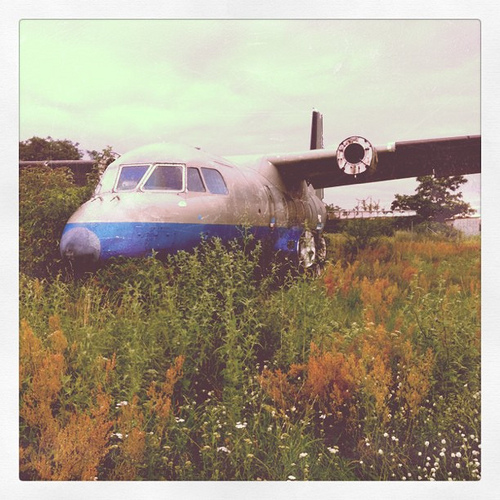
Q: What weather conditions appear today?
A: It is cloudy.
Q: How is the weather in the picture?
A: It is cloudy.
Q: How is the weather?
A: It is cloudy.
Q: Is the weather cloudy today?
A: Yes, it is cloudy.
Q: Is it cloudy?
A: Yes, it is cloudy.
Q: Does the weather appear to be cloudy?
A: Yes, it is cloudy.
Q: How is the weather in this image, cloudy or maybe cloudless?
A: It is cloudy.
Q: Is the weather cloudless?
A: No, it is cloudy.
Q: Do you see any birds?
A: No, there are no birds.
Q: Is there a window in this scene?
A: Yes, there is a window.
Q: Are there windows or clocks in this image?
A: Yes, there is a window.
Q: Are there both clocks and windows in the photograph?
A: No, there is a window but no clocks.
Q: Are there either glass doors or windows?
A: Yes, there is a glass window.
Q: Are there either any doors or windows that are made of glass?
A: Yes, the window is made of glass.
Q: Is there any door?
A: No, there are no doors.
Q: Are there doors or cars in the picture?
A: No, there are no doors or cars.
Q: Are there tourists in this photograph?
A: No, there are no tourists.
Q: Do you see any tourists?
A: No, there are no tourists.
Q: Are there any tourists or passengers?
A: No, there are no tourists or passengers.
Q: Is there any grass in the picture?
A: Yes, there is grass.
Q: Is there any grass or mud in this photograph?
A: Yes, there is grass.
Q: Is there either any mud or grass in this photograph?
A: Yes, there is grass.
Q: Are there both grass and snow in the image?
A: No, there is grass but no snow.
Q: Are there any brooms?
A: No, there are no brooms.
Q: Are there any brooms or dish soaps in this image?
A: No, there are no brooms or dish soaps.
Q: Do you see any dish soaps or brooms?
A: No, there are no brooms or dish soaps.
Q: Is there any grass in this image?
A: Yes, there is grass.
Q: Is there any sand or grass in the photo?
A: Yes, there is grass.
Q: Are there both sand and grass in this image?
A: No, there is grass but no sand.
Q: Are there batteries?
A: No, there are no batteries.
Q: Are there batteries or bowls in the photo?
A: No, there are no batteries or bowls.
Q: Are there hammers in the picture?
A: No, there are no hammers.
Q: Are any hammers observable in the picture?
A: No, there are no hammers.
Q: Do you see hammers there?
A: No, there are no hammers.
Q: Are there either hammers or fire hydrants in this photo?
A: No, there are no hammers or fire hydrants.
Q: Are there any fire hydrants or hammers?
A: No, there are no hammers or fire hydrants.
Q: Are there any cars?
A: No, there are no cars.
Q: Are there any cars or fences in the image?
A: No, there are no cars or fences.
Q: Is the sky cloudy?
A: Yes, the sky is cloudy.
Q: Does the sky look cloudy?
A: Yes, the sky is cloudy.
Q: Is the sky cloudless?
A: No, the sky is cloudy.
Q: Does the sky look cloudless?
A: No, the sky is cloudy.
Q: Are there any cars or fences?
A: No, there are no cars or fences.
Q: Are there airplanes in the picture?
A: Yes, there is an airplane.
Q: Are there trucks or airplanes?
A: Yes, there is an airplane.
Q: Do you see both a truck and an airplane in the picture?
A: No, there is an airplane but no trucks.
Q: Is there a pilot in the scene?
A: No, there are no pilots.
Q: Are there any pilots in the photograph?
A: No, there are no pilots.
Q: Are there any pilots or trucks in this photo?
A: No, there are no pilots or trucks.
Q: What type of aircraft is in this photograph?
A: The aircraft is an airplane.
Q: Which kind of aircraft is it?
A: The aircraft is an airplane.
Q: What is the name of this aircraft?
A: This is an airplane.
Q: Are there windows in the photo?
A: Yes, there are windows.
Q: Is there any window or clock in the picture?
A: Yes, there are windows.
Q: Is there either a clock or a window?
A: Yes, there are windows.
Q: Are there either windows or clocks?
A: Yes, there are windows.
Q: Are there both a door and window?
A: No, there are windows but no doors.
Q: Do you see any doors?
A: No, there are no doors.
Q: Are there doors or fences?
A: No, there are no doors or fences.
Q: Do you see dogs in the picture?
A: No, there are no dogs.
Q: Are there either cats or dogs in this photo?
A: No, there are no dogs or cats.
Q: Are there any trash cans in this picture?
A: No, there are no trash cans.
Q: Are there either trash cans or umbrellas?
A: No, there are no trash cans or umbrellas.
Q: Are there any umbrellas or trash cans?
A: No, there are no trash cans or umbrellas.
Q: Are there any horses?
A: No, there are no horses.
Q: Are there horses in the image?
A: No, there are no horses.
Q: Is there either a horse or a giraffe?
A: No, there are no horses or giraffes.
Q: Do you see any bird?
A: No, there are no birds.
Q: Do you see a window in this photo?
A: Yes, there is a window.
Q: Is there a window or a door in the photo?
A: Yes, there is a window.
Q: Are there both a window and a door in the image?
A: No, there is a window but no doors.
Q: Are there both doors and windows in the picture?
A: No, there is a window but no doors.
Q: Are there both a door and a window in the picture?
A: No, there is a window but no doors.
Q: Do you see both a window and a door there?
A: No, there is a window but no doors.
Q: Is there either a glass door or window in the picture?
A: Yes, there is a glass window.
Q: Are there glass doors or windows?
A: Yes, there is a glass window.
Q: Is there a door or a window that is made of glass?
A: Yes, the window is made of glass.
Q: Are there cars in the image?
A: No, there are no cars.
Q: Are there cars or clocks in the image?
A: No, there are no cars or clocks.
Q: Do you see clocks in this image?
A: No, there are no clocks.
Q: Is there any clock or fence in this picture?
A: No, there are no clocks or fences.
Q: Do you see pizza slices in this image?
A: No, there are no pizza slices.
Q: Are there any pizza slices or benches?
A: No, there are no pizza slices or benches.